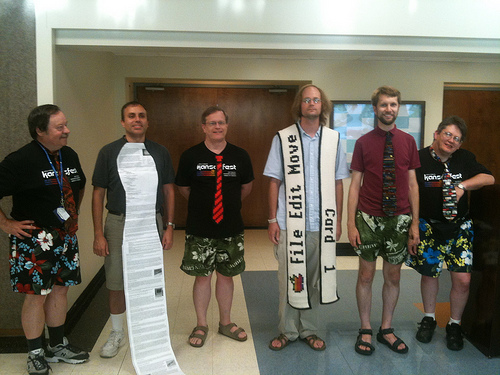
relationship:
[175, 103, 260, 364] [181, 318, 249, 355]
man wearing sandals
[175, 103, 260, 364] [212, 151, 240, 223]
man wearing tie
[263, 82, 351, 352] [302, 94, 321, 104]
man wearing glasses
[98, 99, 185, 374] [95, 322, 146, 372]
man wearing sneakers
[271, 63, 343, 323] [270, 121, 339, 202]
man wearing scarf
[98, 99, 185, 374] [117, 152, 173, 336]
man wearing paper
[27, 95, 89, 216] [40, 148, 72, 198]
man wearing necklace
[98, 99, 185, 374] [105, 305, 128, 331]
man wearing socks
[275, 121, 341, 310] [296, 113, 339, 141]
scarf around neck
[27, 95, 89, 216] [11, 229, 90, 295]
man wearing shorts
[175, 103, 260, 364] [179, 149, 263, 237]
man wearing t-shirt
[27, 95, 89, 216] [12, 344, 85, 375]
man wearing tennis shoes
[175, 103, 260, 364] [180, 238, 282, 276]
man wearing bottoms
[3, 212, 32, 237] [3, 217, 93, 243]
hand on hips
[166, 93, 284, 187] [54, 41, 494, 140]
door in background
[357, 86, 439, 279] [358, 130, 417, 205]
man wearing shirt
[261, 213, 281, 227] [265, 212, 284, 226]
watch on wrist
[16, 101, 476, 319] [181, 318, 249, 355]
men wearing sandals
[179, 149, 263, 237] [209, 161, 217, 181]
t-shirt has symbol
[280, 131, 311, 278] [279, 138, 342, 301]
file edit move on something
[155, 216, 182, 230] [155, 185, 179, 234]
wristwatch on arm